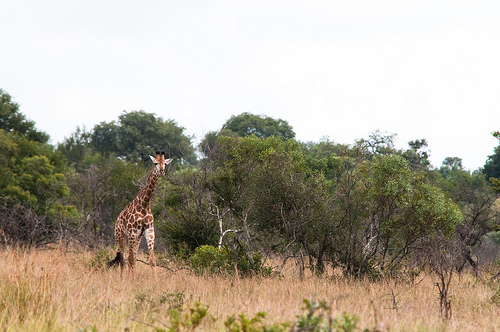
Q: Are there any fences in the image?
A: No, there are no fences.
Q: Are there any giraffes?
A: Yes, there is a giraffe.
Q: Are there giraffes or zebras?
A: Yes, there is a giraffe.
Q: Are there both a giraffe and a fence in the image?
A: No, there is a giraffe but no fences.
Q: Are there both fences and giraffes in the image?
A: No, there is a giraffe but no fences.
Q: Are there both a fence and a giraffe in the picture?
A: No, there is a giraffe but no fences.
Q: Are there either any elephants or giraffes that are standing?
A: Yes, the giraffe is standing.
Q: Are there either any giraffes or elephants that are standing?
A: Yes, the giraffe is standing.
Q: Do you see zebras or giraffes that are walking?
A: Yes, the giraffe is walking.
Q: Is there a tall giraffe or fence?
A: Yes, there is a tall giraffe.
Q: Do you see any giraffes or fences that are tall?
A: Yes, the giraffe is tall.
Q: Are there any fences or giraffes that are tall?
A: Yes, the giraffe is tall.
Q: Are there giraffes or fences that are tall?
A: Yes, the giraffe is tall.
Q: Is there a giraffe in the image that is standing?
A: Yes, there is a giraffe that is standing.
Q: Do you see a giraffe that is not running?
A: Yes, there is a giraffe that is standing .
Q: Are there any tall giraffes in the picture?
A: Yes, there is a tall giraffe.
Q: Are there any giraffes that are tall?
A: Yes, there is a giraffe that is tall.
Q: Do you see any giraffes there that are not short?
A: Yes, there is a tall giraffe.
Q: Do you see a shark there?
A: No, there are no sharks.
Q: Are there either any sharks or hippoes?
A: No, there are no sharks or hippoes.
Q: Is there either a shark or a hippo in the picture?
A: No, there are no sharks or hippoes.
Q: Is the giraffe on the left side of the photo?
A: Yes, the giraffe is on the left of the image.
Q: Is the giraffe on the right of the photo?
A: No, the giraffe is on the left of the image.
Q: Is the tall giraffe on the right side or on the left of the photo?
A: The giraffe is on the left of the image.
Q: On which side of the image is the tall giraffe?
A: The giraffe is on the left of the image.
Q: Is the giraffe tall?
A: Yes, the giraffe is tall.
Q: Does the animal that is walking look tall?
A: Yes, the giraffe is tall.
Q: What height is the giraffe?
A: The giraffe is tall.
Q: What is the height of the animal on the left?
A: The giraffe is tall.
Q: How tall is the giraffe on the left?
A: The giraffe is tall.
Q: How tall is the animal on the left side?
A: The giraffe is tall.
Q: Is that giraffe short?
A: No, the giraffe is tall.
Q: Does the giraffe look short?
A: No, the giraffe is tall.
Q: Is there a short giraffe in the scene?
A: No, there is a giraffe but it is tall.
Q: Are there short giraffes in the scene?
A: No, there is a giraffe but it is tall.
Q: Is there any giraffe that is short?
A: No, there is a giraffe but it is tall.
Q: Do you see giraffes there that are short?
A: No, there is a giraffe but it is tall.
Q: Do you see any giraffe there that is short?
A: No, there is a giraffe but it is tall.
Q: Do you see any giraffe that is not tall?
A: No, there is a giraffe but it is tall.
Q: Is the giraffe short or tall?
A: The giraffe is tall.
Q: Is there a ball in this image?
A: No, there are no balls.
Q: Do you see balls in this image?
A: No, there are no balls.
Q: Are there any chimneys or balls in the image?
A: No, there are no balls or chimneys.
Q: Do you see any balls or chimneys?
A: No, there are no balls or chimneys.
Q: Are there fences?
A: No, there are no fences.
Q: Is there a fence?
A: No, there are no fences.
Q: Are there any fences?
A: No, there are no fences.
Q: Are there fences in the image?
A: No, there are no fences.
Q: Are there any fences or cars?
A: No, there are no fences or cars.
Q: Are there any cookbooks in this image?
A: No, there are no cookbooks.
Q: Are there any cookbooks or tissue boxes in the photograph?
A: No, there are no cookbooks or tissue boxes.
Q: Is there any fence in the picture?
A: No, there are no fences.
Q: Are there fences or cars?
A: No, there are no fences or cars.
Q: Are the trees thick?
A: Yes, the trees are thick.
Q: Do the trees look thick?
A: Yes, the trees are thick.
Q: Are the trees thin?
A: No, the trees are thick.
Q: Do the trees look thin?
A: No, the trees are thick.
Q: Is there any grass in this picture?
A: Yes, there is grass.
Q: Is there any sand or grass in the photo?
A: Yes, there is grass.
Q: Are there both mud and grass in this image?
A: No, there is grass but no mud.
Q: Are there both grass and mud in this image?
A: No, there is grass but no mud.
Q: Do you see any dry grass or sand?
A: Yes, there is dry grass.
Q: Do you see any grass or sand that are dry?
A: Yes, the grass is dry.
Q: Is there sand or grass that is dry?
A: Yes, the grass is dry.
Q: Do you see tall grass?
A: Yes, there is tall grass.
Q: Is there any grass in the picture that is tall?
A: Yes, there is grass that is tall.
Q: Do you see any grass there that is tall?
A: Yes, there is grass that is tall.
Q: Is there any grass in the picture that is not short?
A: Yes, there is tall grass.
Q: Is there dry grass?
A: Yes, there is dry grass.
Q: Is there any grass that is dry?
A: Yes, there is grass that is dry.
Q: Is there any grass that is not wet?
A: Yes, there is dry grass.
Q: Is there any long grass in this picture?
A: Yes, there is long grass.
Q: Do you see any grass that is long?
A: Yes, there is grass that is long.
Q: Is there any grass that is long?
A: Yes, there is grass that is long.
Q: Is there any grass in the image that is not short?
A: Yes, there is long grass.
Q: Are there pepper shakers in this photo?
A: No, there are no pepper shakers.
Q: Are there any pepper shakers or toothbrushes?
A: No, there are no pepper shakers or toothbrushes.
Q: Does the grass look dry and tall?
A: Yes, the grass is dry and tall.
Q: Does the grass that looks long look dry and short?
A: No, the grass is dry but tall.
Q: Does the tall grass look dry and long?
A: Yes, the grass is dry and long.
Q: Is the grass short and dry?
A: No, the grass is dry but long.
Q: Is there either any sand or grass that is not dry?
A: No, there is grass but it is dry.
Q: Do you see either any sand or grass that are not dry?
A: No, there is grass but it is dry.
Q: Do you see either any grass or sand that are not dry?
A: No, there is grass but it is dry.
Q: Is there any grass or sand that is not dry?
A: No, there is grass but it is dry.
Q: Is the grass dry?
A: Yes, the grass is dry.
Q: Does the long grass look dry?
A: Yes, the grass is dry.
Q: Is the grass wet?
A: No, the grass is dry.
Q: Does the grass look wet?
A: No, the grass is dry.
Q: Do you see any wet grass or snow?
A: No, there is grass but it is dry.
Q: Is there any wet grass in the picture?
A: No, there is grass but it is dry.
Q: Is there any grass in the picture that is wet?
A: No, there is grass but it is dry.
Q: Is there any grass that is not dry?
A: No, there is grass but it is dry.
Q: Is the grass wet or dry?
A: The grass is dry.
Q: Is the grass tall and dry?
A: Yes, the grass is tall and dry.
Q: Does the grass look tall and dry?
A: Yes, the grass is tall and dry.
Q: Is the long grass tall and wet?
A: No, the grass is tall but dry.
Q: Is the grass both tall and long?
A: Yes, the grass is tall and long.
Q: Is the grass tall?
A: Yes, the grass is tall.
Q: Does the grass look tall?
A: Yes, the grass is tall.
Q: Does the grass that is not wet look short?
A: No, the grass is tall.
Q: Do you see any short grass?
A: No, there is grass but it is tall.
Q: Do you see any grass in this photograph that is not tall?
A: No, there is grass but it is tall.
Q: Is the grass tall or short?
A: The grass is tall.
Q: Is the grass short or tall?
A: The grass is tall.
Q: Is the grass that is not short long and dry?
A: Yes, the grass is long and dry.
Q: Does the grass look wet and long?
A: No, the grass is long but dry.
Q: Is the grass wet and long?
A: No, the grass is long but dry.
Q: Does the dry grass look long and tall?
A: Yes, the grass is long and tall.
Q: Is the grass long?
A: Yes, the grass is long.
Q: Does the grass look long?
A: Yes, the grass is long.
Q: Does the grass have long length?
A: Yes, the grass is long.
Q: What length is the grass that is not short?
A: The grass is long.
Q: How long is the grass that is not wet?
A: The grass is long.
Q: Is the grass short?
A: No, the grass is long.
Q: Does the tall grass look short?
A: No, the grass is long.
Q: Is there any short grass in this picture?
A: No, there is grass but it is long.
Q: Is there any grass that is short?
A: No, there is grass but it is long.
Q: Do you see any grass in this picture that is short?
A: No, there is grass but it is long.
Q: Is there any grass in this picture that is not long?
A: No, there is grass but it is long.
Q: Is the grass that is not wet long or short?
A: The grass is long.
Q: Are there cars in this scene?
A: No, there are no cars.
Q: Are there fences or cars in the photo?
A: No, there are no cars or fences.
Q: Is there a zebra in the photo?
A: No, there are no zebras.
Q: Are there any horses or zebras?
A: No, there are no zebras or horses.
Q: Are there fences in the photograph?
A: No, there are no fences.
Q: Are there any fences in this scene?
A: No, there are no fences.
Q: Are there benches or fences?
A: No, there are no fences or benches.